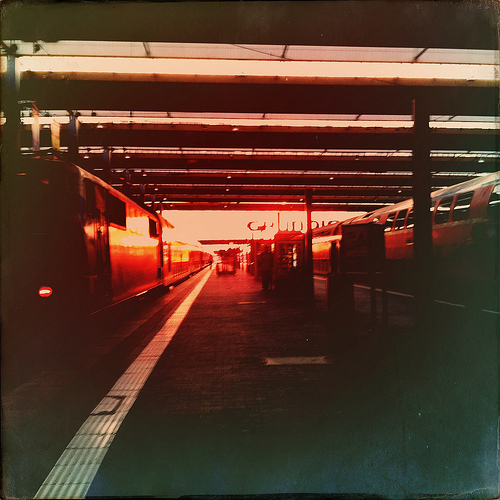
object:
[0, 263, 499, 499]
platform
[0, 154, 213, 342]
subway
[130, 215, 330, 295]
sunset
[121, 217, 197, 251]
sun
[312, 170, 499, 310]
train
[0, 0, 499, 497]
station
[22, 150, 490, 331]
traffic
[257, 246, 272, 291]
people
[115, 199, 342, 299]
dusk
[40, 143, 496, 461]
stop